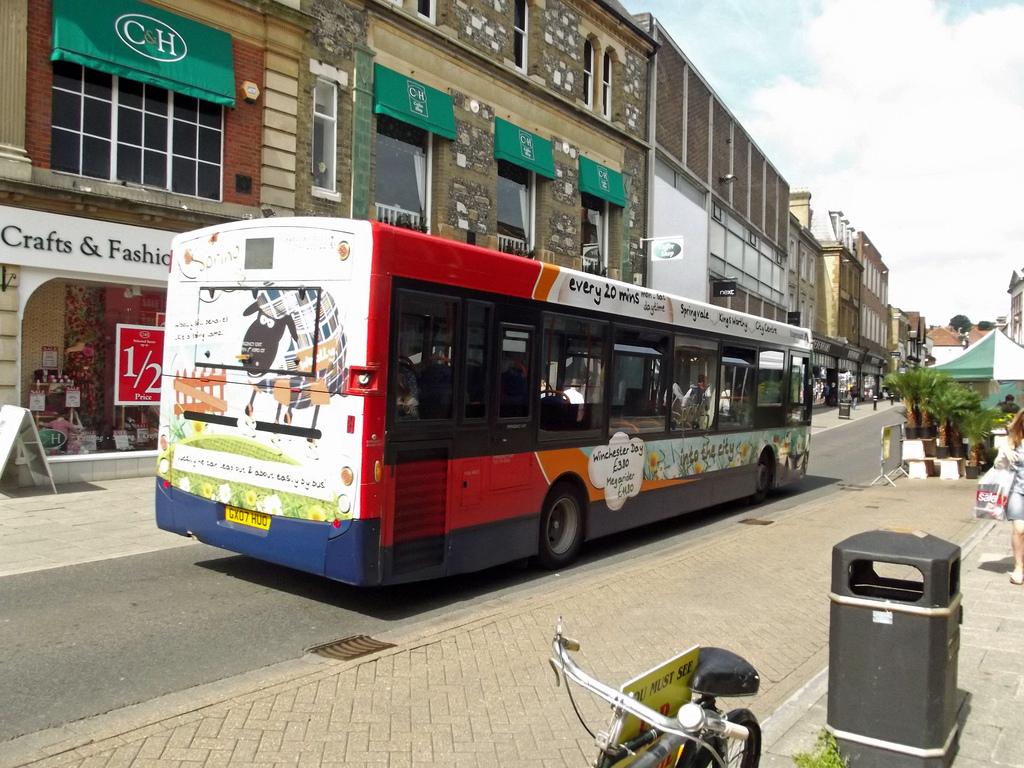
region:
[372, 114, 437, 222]
a window on a building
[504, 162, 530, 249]
a window on a building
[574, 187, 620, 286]
a window on a building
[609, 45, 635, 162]
a window on a building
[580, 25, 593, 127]
a window on a building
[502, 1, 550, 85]
a window on a building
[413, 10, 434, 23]
a window on a building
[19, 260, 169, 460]
a window on a building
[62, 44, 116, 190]
a window on a building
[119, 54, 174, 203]
a window on a building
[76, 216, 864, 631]
the bus is driving down the street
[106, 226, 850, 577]
the bus is multi colored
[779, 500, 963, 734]
the garbage can is black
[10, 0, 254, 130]
the awning over the window is green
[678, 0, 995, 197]
the sky is partly cloudy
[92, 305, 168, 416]
the sign in the window is square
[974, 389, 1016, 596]
the woman is holding a bag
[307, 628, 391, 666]
storm drain grate on the road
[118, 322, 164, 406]
1/2 off price sign in the window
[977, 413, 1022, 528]
woman carrying a bag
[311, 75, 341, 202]
window on the building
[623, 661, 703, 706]
sign up against the bike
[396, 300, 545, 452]
windows on the bus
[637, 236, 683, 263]
green and white sign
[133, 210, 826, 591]
Red blue and white bus along street.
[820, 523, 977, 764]
Grey trash can along street.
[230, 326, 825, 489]
bus on the street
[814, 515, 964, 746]
trash can on the sidewalk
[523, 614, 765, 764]
bike parked on the sidewalk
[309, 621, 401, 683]
drain vent against the curb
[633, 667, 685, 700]
yellow sign againist the bike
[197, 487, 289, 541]
back license plate on the bus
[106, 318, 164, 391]
red and white sign behind the bus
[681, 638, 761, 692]
black seat on the bike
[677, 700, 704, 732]
white circle on the bike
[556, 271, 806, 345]
black lettering on he bus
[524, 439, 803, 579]
tires on the bus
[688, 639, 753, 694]
black seat on the bicycle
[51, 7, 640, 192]
green canopies over the windows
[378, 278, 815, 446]
windows on the bus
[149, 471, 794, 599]
blue stripe on the bus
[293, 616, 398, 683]
grate on the street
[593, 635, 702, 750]
sign leaning against the bicycle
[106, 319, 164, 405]
red and white poster on the store window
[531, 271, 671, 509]
orange stripe on the bus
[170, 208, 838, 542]
bus stopped on the street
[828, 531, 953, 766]
black trashcan on the sidewalk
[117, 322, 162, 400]
red sign with white numbers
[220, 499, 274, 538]
yellow license plate on the bus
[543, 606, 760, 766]
bicycle on the sidewalk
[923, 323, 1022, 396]
green and white umbrella canopy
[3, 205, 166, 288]
black lettering on storefront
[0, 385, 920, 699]
street the bus is on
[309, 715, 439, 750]
the sidewalk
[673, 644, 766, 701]
a seat on the bike